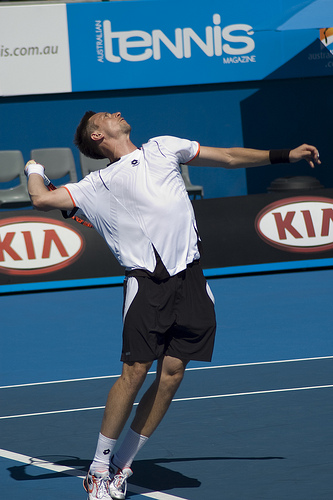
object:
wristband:
[269, 145, 290, 162]